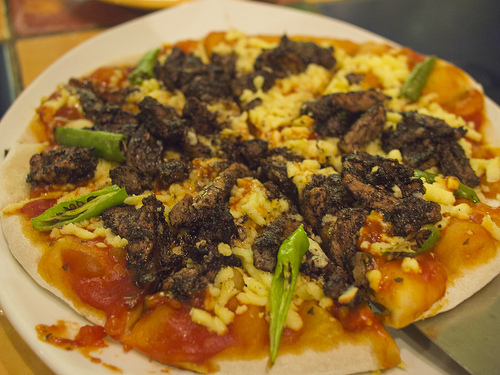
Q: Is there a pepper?
A: Yes, there is a pepper.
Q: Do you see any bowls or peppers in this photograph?
A: Yes, there is a pepper.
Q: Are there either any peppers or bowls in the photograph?
A: Yes, there is a pepper.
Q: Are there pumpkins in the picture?
A: No, there are no pumpkins.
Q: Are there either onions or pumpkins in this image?
A: No, there are no pumpkins or onions.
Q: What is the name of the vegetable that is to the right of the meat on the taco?
A: The vegetable is a pepper.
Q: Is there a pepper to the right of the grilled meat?
A: Yes, there is a pepper to the right of the meat.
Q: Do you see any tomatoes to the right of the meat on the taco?
A: No, there is a pepper to the right of the meat.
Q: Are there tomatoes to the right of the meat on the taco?
A: No, there is a pepper to the right of the meat.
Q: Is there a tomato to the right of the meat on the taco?
A: No, there is a pepper to the right of the meat.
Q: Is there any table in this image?
A: Yes, there is a table.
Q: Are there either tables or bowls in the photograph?
A: Yes, there is a table.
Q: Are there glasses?
A: No, there are no glasses.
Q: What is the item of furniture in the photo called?
A: The piece of furniture is a table.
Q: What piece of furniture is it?
A: The piece of furniture is a table.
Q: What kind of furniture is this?
A: This is a table.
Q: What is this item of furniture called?
A: This is a table.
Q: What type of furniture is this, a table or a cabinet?
A: This is a table.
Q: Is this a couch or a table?
A: This is a table.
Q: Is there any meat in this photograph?
A: Yes, there is meat.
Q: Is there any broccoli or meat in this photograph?
A: Yes, there is meat.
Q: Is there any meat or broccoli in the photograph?
A: Yes, there is meat.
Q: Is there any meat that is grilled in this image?
A: Yes, there is grilled meat.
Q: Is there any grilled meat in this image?
A: Yes, there is grilled meat.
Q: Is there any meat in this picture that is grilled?
A: Yes, there is meat that is grilled.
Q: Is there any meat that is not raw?
A: Yes, there is grilled meat.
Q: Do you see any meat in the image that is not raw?
A: Yes, there is grilled meat.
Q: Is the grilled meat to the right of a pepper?
A: No, the meat is to the left of a pepper.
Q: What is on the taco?
A: The meat is on the taco.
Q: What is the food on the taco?
A: The food is meat.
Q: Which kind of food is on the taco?
A: The food is meat.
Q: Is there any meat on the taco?
A: Yes, there is meat on the taco.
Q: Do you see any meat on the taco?
A: Yes, there is meat on the taco.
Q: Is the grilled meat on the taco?
A: Yes, the meat is on the taco.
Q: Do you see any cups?
A: No, there are no cups.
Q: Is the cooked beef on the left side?
A: Yes, the beef is on the left of the image.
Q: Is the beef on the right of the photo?
A: No, the beef is on the left of the image.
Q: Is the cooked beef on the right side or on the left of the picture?
A: The beef is on the left of the image.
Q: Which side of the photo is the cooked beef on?
A: The beef is on the left of the image.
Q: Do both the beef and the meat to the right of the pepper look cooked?
A: Yes, both the beef and the meat are cooked.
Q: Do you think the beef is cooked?
A: Yes, the beef is cooked.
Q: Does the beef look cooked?
A: Yes, the beef is cooked.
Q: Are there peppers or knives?
A: Yes, there is a pepper.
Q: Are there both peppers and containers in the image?
A: No, there is a pepper but no containers.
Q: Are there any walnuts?
A: No, there are no walnuts.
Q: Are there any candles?
A: No, there are no candles.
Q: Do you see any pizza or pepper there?
A: Yes, there is a pepper.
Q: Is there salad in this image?
A: No, there is no salad.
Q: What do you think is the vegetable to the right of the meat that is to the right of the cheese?
A: The vegetable is a pepper.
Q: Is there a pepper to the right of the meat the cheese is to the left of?
A: Yes, there is a pepper to the right of the meat.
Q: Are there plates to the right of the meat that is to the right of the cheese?
A: No, there is a pepper to the right of the meat.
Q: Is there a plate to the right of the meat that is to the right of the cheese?
A: No, there is a pepper to the right of the meat.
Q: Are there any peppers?
A: Yes, there is a pepper.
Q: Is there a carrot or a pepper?
A: Yes, there is a pepper.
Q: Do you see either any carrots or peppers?
A: Yes, there is a pepper.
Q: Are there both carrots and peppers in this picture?
A: No, there is a pepper but no carrots.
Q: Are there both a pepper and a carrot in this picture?
A: No, there is a pepper but no carrots.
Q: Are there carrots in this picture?
A: No, there are no carrots.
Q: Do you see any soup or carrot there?
A: No, there are no carrots or soup.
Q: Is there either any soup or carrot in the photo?
A: No, there are no carrots or soup.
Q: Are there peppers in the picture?
A: Yes, there is a pepper.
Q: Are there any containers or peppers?
A: Yes, there is a pepper.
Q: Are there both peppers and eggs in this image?
A: No, there is a pepper but no eggs.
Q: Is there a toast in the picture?
A: No, there are no toasts.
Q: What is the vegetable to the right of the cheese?
A: The vegetable is a pepper.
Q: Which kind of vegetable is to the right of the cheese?
A: The vegetable is a pepper.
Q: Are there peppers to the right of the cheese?
A: Yes, there is a pepper to the right of the cheese.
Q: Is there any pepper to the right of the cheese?
A: Yes, there is a pepper to the right of the cheese.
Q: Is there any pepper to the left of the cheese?
A: No, the pepper is to the right of the cheese.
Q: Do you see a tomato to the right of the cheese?
A: No, there is a pepper to the right of the cheese.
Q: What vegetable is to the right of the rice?
A: The vegetable is a pepper.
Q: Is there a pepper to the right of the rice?
A: Yes, there is a pepper to the right of the rice.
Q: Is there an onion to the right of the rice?
A: No, there is a pepper to the right of the rice.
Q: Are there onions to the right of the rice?
A: No, there is a pepper to the right of the rice.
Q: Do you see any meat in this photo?
A: Yes, there is meat.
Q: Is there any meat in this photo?
A: Yes, there is meat.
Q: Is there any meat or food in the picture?
A: Yes, there is meat.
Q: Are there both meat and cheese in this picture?
A: Yes, there are both meat and cheese.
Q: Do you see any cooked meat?
A: Yes, there is cooked meat.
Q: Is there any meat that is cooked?
A: Yes, there is meat that is cooked.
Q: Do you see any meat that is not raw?
A: Yes, there is cooked meat.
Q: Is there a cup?
A: No, there are no cups.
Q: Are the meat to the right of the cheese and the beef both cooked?
A: Yes, both the meat and the beef are cooked.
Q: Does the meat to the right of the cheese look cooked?
A: Yes, the meat is cooked.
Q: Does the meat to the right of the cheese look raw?
A: No, the meat is cooked.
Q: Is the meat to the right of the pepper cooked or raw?
A: The meat is cooked.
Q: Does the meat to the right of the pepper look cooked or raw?
A: The meat is cooked.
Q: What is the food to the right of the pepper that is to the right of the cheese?
A: The food is meat.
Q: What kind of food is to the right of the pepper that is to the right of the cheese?
A: The food is meat.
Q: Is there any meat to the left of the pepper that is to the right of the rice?
A: No, the meat is to the right of the pepper.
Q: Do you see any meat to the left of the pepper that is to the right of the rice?
A: No, the meat is to the right of the pepper.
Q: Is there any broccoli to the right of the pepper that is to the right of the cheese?
A: No, there is meat to the right of the pepper.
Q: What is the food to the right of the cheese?
A: The food is meat.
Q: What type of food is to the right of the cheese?
A: The food is meat.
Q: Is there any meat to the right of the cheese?
A: Yes, there is meat to the right of the cheese.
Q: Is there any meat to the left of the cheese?
A: No, the meat is to the right of the cheese.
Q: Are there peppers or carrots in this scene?
A: Yes, there is a pepper.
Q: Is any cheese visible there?
A: Yes, there is cheese.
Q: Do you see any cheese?
A: Yes, there is cheese.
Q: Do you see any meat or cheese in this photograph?
A: Yes, there is cheese.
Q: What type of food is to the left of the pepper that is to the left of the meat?
A: The food is cheese.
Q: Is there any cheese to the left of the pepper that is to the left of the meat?
A: Yes, there is cheese to the left of the pepper.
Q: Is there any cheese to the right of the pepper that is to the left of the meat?
A: No, the cheese is to the left of the pepper.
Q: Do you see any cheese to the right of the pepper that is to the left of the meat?
A: No, the cheese is to the left of the pepper.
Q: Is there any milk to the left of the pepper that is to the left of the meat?
A: No, there is cheese to the left of the pepper.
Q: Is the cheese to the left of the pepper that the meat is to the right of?
A: Yes, the cheese is to the left of the pepper.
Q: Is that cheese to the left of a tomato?
A: No, the cheese is to the left of the pepper.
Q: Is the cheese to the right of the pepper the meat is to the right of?
A: No, the cheese is to the left of the pepper.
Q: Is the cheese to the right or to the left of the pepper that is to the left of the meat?
A: The cheese is to the left of the pepper.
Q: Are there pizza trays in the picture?
A: No, there are no pizza trays.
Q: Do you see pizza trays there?
A: No, there are no pizza trays.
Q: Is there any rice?
A: Yes, there is rice.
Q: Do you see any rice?
A: Yes, there is rice.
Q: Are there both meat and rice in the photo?
A: Yes, there are both rice and meat.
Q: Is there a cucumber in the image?
A: No, there are no cucumbers.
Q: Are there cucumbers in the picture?
A: No, there are no cucumbers.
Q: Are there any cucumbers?
A: No, there are no cucumbers.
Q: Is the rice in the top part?
A: No, the rice is in the bottom of the image.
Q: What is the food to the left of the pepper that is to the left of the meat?
A: The food is rice.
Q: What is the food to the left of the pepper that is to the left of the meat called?
A: The food is rice.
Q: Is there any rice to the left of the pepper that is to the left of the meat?
A: Yes, there is rice to the left of the pepper.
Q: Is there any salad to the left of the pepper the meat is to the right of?
A: No, there is rice to the left of the pepper.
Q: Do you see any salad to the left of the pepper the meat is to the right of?
A: No, there is rice to the left of the pepper.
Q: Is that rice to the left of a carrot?
A: No, the rice is to the left of a pepper.